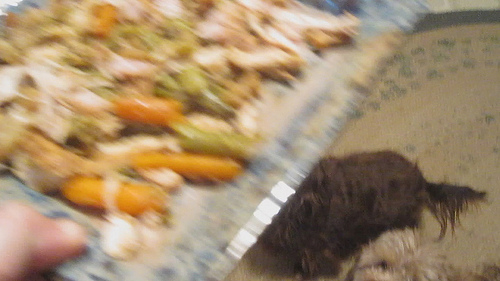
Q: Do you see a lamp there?
A: No, there are no lamps.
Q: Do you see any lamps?
A: No, there are no lamps.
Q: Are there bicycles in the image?
A: No, there are no bicycles.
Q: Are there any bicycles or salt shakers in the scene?
A: No, there are no bicycles or salt shakers.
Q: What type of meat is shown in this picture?
A: The meat is chicken.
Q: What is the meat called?
A: The meat is chicken.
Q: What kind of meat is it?
A: The meat is chicken.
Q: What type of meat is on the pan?
A: The meat is chicken.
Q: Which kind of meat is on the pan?
A: The meat is chicken.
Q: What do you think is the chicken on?
A: The chicken is on the pan.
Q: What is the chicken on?
A: The chicken is on the pan.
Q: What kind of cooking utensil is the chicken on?
A: The chicken is on the pan.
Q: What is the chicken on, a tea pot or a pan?
A: The chicken is on a pan.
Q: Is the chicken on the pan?
A: Yes, the chicken is on the pan.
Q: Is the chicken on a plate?
A: No, the chicken is on the pan.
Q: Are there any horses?
A: No, there are no horses.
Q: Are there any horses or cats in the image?
A: No, there are no horses or cats.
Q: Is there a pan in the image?
A: Yes, there is a pan.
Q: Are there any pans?
A: Yes, there is a pan.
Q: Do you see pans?
A: Yes, there is a pan.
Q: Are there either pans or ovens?
A: Yes, there is a pan.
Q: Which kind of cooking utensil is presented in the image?
A: The cooking utensil is a pan.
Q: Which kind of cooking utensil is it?
A: The cooking utensil is a pan.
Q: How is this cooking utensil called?
A: This is a pan.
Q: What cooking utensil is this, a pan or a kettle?
A: This is a pan.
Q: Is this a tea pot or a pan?
A: This is a pan.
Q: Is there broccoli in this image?
A: Yes, there is broccoli.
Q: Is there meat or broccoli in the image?
A: Yes, there is broccoli.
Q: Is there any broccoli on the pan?
A: Yes, there is broccoli on the pan.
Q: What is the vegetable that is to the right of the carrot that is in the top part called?
A: The vegetable is broccoli.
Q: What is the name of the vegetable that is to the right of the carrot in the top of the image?
A: The vegetable is broccoli.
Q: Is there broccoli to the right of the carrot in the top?
A: Yes, there is broccoli to the right of the carrot.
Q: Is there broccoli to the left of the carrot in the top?
A: No, the broccoli is to the right of the carrot.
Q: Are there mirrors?
A: No, there are no mirrors.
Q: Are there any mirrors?
A: No, there are no mirrors.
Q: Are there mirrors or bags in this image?
A: No, there are no mirrors or bags.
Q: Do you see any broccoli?
A: Yes, there is broccoli.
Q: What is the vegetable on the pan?
A: The vegetable is broccoli.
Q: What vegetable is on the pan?
A: The vegetable is broccoli.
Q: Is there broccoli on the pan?
A: Yes, there is broccoli on the pan.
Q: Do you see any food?
A: Yes, there is food.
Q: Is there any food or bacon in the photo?
A: Yes, there is food.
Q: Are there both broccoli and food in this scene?
A: Yes, there are both food and broccoli.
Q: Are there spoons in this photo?
A: No, there are no spoons.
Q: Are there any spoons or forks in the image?
A: No, there are no spoons or forks.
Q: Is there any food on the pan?
A: Yes, there is food on the pan.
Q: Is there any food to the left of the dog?
A: Yes, there is food to the left of the dog.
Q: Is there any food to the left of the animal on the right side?
A: Yes, there is food to the left of the dog.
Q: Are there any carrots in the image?
A: Yes, there is a carrot.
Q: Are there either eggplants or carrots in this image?
A: Yes, there is a carrot.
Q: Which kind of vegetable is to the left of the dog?
A: The vegetable is a carrot.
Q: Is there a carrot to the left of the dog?
A: Yes, there is a carrot to the left of the dog.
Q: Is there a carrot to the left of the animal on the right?
A: Yes, there is a carrot to the left of the dog.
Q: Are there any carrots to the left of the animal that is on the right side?
A: Yes, there is a carrot to the left of the dog.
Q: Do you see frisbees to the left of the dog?
A: No, there is a carrot to the left of the dog.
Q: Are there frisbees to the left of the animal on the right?
A: No, there is a carrot to the left of the dog.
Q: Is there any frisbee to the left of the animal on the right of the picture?
A: No, there is a carrot to the left of the dog.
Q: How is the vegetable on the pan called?
A: The vegetable is a carrot.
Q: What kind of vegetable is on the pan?
A: The vegetable is a carrot.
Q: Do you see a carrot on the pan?
A: Yes, there is a carrot on the pan.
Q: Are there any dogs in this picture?
A: Yes, there is a dog.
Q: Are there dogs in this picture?
A: Yes, there is a dog.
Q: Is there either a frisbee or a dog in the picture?
A: Yes, there is a dog.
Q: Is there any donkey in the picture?
A: No, there are no donkeys.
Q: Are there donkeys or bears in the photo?
A: No, there are no donkeys or bears.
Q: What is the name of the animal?
A: The animal is a dog.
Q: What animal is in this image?
A: The animal is a dog.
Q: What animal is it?
A: The animal is a dog.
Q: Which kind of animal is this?
A: This is a dog.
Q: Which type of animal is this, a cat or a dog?
A: This is a dog.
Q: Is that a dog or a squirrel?
A: That is a dog.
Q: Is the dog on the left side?
A: No, the dog is on the right of the image.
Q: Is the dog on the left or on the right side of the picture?
A: The dog is on the right of the image.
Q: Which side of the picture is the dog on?
A: The dog is on the right of the image.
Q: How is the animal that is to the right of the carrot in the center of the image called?
A: The animal is a dog.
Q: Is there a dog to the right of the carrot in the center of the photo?
A: Yes, there is a dog to the right of the carrot.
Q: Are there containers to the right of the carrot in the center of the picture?
A: No, there is a dog to the right of the carrot.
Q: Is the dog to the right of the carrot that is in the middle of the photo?
A: Yes, the dog is to the right of the carrot.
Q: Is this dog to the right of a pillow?
A: No, the dog is to the right of the carrot.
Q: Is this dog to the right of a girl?
A: No, the dog is to the right of a carrot.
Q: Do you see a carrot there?
A: Yes, there is a carrot.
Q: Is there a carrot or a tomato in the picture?
A: Yes, there is a carrot.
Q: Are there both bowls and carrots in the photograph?
A: No, there is a carrot but no bowls.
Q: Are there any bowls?
A: No, there are no bowls.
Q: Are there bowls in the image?
A: No, there are no bowls.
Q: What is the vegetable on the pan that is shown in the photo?
A: The vegetable is a carrot.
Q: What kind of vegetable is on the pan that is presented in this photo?
A: The vegetable is a carrot.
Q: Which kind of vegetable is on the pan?
A: The vegetable is a carrot.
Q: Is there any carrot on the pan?
A: Yes, there is a carrot on the pan.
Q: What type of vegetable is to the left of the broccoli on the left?
A: The vegetable is a carrot.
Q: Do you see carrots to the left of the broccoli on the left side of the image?
A: Yes, there is a carrot to the left of the broccoli.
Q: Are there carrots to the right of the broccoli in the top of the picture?
A: No, the carrot is to the left of the broccoli.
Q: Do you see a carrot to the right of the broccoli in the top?
A: No, the carrot is to the left of the broccoli.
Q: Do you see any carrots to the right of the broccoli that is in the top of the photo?
A: No, the carrot is to the left of the broccoli.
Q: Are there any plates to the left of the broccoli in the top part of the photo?
A: No, there is a carrot to the left of the broccoli.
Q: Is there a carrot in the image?
A: Yes, there is a carrot.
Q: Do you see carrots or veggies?
A: Yes, there is a carrot.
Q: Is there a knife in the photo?
A: No, there are no knives.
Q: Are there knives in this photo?
A: No, there are no knives.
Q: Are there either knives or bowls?
A: No, there are no knives or bowls.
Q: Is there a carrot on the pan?
A: Yes, there is a carrot on the pan.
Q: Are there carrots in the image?
A: Yes, there is a carrot.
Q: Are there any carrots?
A: Yes, there is a carrot.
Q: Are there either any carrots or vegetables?
A: Yes, there is a carrot.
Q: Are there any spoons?
A: No, there are no spoons.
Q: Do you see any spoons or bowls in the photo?
A: No, there are no spoons or bowls.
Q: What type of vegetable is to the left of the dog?
A: The vegetable is a carrot.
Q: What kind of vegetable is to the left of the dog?
A: The vegetable is a carrot.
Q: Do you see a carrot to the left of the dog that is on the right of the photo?
A: Yes, there is a carrot to the left of the dog.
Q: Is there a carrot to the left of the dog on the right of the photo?
A: Yes, there is a carrot to the left of the dog.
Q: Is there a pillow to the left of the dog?
A: No, there is a carrot to the left of the dog.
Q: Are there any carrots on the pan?
A: Yes, there is a carrot on the pan.